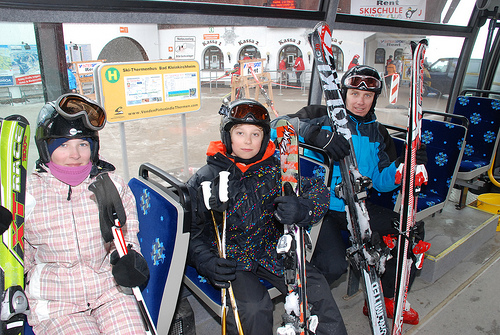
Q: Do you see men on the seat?
A: Yes, there is a man on the seat.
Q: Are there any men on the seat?
A: Yes, there is a man on the seat.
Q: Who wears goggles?
A: The man wears goggles.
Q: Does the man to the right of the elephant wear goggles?
A: Yes, the man wears goggles.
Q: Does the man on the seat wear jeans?
A: No, the man wears goggles.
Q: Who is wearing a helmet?
A: The man is wearing a helmet.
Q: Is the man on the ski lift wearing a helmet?
A: Yes, the man is wearing a helmet.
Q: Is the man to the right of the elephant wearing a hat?
A: No, the man is wearing a helmet.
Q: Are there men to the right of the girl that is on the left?
A: Yes, there is a man to the right of the girl.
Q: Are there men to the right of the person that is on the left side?
A: Yes, there is a man to the right of the girl.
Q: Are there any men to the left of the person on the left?
A: No, the man is to the right of the girl.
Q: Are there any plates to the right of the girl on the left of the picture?
A: No, there is a man to the right of the girl.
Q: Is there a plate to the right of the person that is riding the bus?
A: No, there is a man to the right of the girl.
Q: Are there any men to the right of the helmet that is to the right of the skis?
A: Yes, there is a man to the right of the helmet.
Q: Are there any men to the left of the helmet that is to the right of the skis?
A: No, the man is to the right of the helmet.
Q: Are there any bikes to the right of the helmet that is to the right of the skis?
A: No, there is a man to the right of the helmet.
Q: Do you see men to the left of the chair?
A: Yes, there is a man to the left of the chair.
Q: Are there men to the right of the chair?
A: No, the man is to the left of the chair.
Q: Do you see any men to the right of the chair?
A: No, the man is to the left of the chair.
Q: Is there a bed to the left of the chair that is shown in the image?
A: No, there is a man to the left of the chair.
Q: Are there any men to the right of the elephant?
A: Yes, there is a man to the right of the elephant.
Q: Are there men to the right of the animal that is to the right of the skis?
A: Yes, there is a man to the right of the elephant.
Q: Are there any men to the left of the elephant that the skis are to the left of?
A: No, the man is to the right of the elephant.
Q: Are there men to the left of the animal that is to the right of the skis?
A: No, the man is to the right of the elephant.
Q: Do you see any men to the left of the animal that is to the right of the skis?
A: No, the man is to the right of the elephant.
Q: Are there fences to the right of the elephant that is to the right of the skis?
A: No, there is a man to the right of the elephant.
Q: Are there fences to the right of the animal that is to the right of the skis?
A: No, there is a man to the right of the elephant.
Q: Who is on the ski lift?
A: The man is on the ski lift.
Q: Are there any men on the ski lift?
A: Yes, there is a man on the ski lift.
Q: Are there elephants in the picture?
A: Yes, there is an elephant.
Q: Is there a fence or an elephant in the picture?
A: Yes, there is an elephant.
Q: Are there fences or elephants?
A: Yes, there is an elephant.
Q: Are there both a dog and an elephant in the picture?
A: No, there is an elephant but no dogs.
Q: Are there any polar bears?
A: No, there are no polar bears.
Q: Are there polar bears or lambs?
A: No, there are no polar bears or lambs.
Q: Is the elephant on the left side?
A: Yes, the elephant is on the left of the image.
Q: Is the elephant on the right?
A: No, the elephant is on the left of the image.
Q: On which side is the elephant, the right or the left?
A: The elephant is on the left of the image.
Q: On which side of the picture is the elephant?
A: The elephant is on the left of the image.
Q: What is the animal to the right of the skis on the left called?
A: The animal is an elephant.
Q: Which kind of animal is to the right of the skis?
A: The animal is an elephant.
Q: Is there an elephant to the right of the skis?
A: Yes, there is an elephant to the right of the skis.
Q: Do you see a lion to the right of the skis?
A: No, there is an elephant to the right of the skis.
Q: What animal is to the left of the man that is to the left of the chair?
A: The animal is an elephant.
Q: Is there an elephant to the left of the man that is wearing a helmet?
A: Yes, there is an elephant to the left of the man.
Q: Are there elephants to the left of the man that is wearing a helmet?
A: Yes, there is an elephant to the left of the man.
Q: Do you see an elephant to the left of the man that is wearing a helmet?
A: Yes, there is an elephant to the left of the man.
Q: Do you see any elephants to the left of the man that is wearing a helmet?
A: Yes, there is an elephant to the left of the man.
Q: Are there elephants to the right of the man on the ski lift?
A: No, the elephant is to the left of the man.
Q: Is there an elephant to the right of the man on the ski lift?
A: No, the elephant is to the left of the man.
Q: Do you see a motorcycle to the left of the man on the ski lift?
A: No, there is an elephant to the left of the man.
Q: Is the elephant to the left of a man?
A: Yes, the elephant is to the left of a man.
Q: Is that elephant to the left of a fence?
A: No, the elephant is to the left of a man.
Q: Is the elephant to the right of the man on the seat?
A: No, the elephant is to the left of the man.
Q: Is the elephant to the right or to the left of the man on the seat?
A: The elephant is to the left of the man.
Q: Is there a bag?
A: No, there are no bags.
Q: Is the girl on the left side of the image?
A: Yes, the girl is on the left of the image.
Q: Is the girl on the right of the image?
A: No, the girl is on the left of the image.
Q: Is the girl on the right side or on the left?
A: The girl is on the left of the image.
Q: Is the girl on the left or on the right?
A: The girl is on the left of the image.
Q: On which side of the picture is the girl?
A: The girl is on the left of the image.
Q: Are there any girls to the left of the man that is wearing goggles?
A: Yes, there is a girl to the left of the man.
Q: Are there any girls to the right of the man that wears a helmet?
A: No, the girl is to the left of the man.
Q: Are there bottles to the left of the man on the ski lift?
A: No, there is a girl to the left of the man.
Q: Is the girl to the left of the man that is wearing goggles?
A: Yes, the girl is to the left of the man.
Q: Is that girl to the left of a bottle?
A: No, the girl is to the left of the man.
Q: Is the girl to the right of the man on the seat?
A: No, the girl is to the left of the man.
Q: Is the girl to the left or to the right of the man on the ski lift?
A: The girl is to the left of the man.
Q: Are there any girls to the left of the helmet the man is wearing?
A: Yes, there is a girl to the left of the helmet.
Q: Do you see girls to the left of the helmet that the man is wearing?
A: Yes, there is a girl to the left of the helmet.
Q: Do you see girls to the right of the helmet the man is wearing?
A: No, the girl is to the left of the helmet.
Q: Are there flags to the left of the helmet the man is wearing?
A: No, there is a girl to the left of the helmet.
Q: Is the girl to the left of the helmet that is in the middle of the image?
A: Yes, the girl is to the left of the helmet.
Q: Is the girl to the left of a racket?
A: No, the girl is to the left of the helmet.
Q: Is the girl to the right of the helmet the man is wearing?
A: No, the girl is to the left of the helmet.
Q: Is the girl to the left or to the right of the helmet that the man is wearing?
A: The girl is to the left of the helmet.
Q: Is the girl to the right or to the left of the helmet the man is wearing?
A: The girl is to the left of the helmet.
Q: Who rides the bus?
A: The girl rides the bus.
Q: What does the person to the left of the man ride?
A: The girl rides the bus.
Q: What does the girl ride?
A: The girl rides the bus.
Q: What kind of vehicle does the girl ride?
A: The girl rides the bus.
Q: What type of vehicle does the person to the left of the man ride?
A: The girl rides the bus.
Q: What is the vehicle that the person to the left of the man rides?
A: The vehicle is a bus.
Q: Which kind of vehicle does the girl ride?
A: The girl rides the bus.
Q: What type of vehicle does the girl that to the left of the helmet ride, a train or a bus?
A: The girl rides a bus.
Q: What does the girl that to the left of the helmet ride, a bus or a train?
A: The girl rides a bus.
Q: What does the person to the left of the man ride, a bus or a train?
A: The girl rides a bus.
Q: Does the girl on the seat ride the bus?
A: Yes, the girl rides the bus.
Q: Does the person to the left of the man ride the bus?
A: Yes, the girl rides the bus.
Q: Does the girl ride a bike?
A: No, the girl rides the bus.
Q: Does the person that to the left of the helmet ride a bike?
A: No, the girl rides the bus.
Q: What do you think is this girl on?
A: The girl is on the seat.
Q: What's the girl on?
A: The girl is on the seat.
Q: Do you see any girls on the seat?
A: Yes, there is a girl on the seat.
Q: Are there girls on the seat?
A: Yes, there is a girl on the seat.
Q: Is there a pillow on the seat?
A: No, there is a girl on the seat.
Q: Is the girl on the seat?
A: Yes, the girl is on the seat.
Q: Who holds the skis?
A: The girl holds the skis.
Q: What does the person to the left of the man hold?
A: The girl holds the skis.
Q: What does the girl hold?
A: The girl holds the skis.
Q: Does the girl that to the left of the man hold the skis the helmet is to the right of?
A: Yes, the girl holds the skis.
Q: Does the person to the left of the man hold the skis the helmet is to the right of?
A: Yes, the girl holds the skis.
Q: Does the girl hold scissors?
A: No, the girl holds the skis.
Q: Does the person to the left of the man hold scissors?
A: No, the girl holds the skis.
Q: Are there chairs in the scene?
A: Yes, there is a chair.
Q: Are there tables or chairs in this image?
A: Yes, there is a chair.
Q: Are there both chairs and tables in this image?
A: No, there is a chair but no tables.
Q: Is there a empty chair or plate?
A: Yes, there is an empty chair.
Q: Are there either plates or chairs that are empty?
A: Yes, the chair is empty.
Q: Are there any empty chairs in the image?
A: Yes, there is an empty chair.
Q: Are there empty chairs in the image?
A: Yes, there is an empty chair.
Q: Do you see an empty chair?
A: Yes, there is an empty chair.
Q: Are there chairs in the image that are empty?
A: Yes, there is a chair that is empty.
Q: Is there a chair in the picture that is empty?
A: Yes, there is a chair that is empty.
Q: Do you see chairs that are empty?
A: Yes, there is a chair that is empty.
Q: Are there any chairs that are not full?
A: Yes, there is a empty chair.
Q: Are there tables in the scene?
A: No, there are no tables.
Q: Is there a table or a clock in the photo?
A: No, there are no tables or clocks.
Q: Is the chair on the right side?
A: Yes, the chair is on the right of the image.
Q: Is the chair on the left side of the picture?
A: No, the chair is on the right of the image.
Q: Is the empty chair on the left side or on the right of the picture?
A: The chair is on the right of the image.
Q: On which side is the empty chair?
A: The chair is on the right of the image.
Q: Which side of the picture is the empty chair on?
A: The chair is on the right of the image.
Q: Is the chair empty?
A: Yes, the chair is empty.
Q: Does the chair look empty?
A: Yes, the chair is empty.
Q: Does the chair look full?
A: No, the chair is empty.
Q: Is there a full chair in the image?
A: No, there is a chair but it is empty.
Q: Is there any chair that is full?
A: No, there is a chair but it is empty.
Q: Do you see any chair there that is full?
A: No, there is a chair but it is empty.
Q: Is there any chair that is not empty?
A: No, there is a chair but it is empty.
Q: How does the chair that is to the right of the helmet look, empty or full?
A: The chair is empty.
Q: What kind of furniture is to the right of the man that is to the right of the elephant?
A: The piece of furniture is a chair.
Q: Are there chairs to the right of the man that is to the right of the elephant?
A: Yes, there is a chair to the right of the man.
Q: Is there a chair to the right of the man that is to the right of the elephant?
A: Yes, there is a chair to the right of the man.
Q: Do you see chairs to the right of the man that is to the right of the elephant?
A: Yes, there is a chair to the right of the man.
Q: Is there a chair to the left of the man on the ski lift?
A: No, the chair is to the right of the man.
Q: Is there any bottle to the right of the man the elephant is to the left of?
A: No, there is a chair to the right of the man.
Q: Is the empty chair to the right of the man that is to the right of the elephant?
A: Yes, the chair is to the right of the man.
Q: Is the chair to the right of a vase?
A: No, the chair is to the right of the man.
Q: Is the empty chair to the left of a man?
A: No, the chair is to the right of a man.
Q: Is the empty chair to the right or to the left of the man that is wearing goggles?
A: The chair is to the right of the man.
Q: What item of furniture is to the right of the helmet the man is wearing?
A: The piece of furniture is a chair.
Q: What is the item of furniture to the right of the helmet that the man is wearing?
A: The piece of furniture is a chair.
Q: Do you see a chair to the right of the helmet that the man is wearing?
A: Yes, there is a chair to the right of the helmet.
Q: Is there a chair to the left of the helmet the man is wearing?
A: No, the chair is to the right of the helmet.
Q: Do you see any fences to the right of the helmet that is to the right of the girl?
A: No, there is a chair to the right of the helmet.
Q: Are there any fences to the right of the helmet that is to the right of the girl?
A: No, there is a chair to the right of the helmet.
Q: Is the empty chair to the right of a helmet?
A: Yes, the chair is to the right of a helmet.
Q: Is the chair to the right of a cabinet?
A: No, the chair is to the right of a helmet.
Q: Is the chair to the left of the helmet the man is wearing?
A: No, the chair is to the right of the helmet.